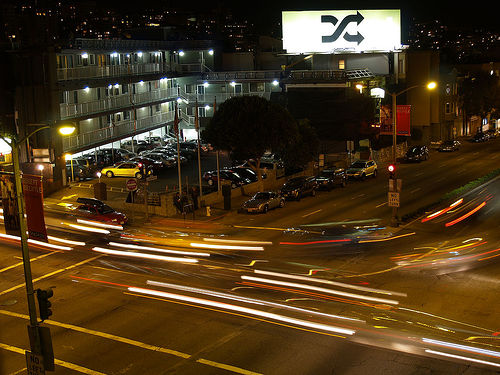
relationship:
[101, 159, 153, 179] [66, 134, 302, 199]
car inside lot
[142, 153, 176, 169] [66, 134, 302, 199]
car inside lot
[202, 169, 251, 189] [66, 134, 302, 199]
car inside lot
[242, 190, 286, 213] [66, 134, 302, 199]
car outside lot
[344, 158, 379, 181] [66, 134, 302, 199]
car outside lot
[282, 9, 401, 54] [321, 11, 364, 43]
sign has arrow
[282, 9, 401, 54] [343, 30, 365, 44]
sign has arrow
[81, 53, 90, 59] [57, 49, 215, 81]
outside lighting on floor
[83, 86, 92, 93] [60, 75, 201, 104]
outside lighting on floor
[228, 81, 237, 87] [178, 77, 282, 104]
outside lighting on floor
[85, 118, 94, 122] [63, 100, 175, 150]
outside lighting on floor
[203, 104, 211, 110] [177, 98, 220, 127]
outside lighting on floor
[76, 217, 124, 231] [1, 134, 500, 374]
light on street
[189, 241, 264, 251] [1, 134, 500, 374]
light on street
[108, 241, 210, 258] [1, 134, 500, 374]
light on street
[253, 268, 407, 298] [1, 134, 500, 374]
light on street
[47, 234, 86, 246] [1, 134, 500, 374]
light on street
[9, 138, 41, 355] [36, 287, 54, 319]
lamppost with traffic light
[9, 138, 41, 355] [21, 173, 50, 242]
lamppost with banner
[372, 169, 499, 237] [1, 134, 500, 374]
island in middle of street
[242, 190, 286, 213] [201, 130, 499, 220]
car parked along curb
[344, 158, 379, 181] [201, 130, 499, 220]
car parked along curb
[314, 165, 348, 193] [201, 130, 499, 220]
car parked along curb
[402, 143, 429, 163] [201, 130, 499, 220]
car parked along curb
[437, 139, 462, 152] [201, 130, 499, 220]
car parked along curb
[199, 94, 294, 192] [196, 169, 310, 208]
tree above wall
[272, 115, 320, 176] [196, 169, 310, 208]
tree above wall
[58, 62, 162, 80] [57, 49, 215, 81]
railing across floor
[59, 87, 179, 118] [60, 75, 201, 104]
railing across floor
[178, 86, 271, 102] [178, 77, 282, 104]
railing across floor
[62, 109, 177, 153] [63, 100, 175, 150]
railing across floor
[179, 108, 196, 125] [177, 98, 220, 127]
railing across floor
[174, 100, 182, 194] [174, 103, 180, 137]
pole with flag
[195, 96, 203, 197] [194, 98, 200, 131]
pole with flag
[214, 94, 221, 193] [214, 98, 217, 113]
pole with flag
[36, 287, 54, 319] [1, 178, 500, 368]
traffic light above traffic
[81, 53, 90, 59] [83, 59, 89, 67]
outside lighting on balcony door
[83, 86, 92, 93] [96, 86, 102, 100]
outside lighting on balcony door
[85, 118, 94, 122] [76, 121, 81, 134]
outside lighting on balcony door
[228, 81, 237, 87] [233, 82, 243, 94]
outside lighting on balcony door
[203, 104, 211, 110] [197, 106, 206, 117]
outside lighting on balcony door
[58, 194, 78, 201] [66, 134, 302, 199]
arrow in lot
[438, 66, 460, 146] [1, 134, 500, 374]
storefront building along street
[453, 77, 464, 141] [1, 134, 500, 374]
storefront building along street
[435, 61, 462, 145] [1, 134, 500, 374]
storefront building along street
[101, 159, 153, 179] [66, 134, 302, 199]
car parked in lot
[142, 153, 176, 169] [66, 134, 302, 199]
car parked in lot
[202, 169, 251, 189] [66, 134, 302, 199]
car parked in lot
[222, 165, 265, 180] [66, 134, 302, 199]
car parked in lot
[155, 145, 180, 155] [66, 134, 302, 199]
car parked in lot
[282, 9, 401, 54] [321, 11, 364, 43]
sign with arrow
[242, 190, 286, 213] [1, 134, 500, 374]
car parked on side of street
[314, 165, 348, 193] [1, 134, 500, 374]
car parked on side of street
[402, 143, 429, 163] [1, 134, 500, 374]
car parked on side of street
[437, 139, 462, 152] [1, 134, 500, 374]
car parked on side of street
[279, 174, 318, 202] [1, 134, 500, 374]
car parked on side of street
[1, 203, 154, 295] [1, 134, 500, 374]
part of street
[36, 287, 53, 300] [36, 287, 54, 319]
part of traffic light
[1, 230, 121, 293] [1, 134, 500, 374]
pedestrian crosswalk on street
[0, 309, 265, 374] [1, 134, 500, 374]
pedestrian crosswalk on street